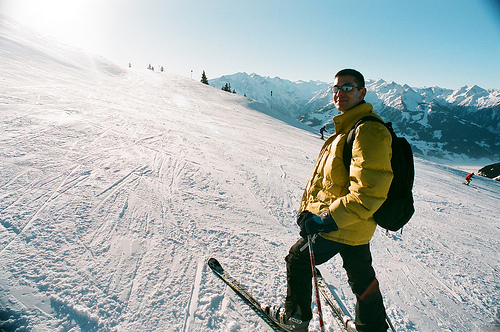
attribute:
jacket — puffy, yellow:
[299, 106, 397, 247]